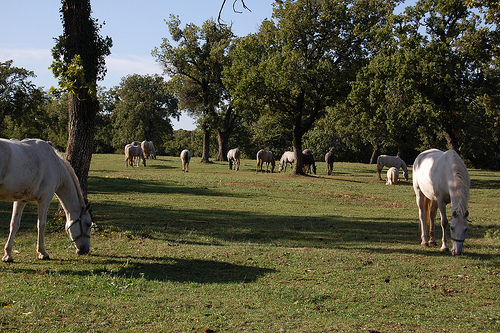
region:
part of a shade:
[222, 205, 262, 252]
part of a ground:
[292, 263, 322, 300]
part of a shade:
[222, 245, 261, 280]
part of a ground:
[343, 255, 397, 312]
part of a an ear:
[443, 202, 448, 214]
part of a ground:
[328, 267, 368, 308]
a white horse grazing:
[1, 133, 90, 263]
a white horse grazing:
[409, 145, 466, 254]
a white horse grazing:
[373, 153, 409, 184]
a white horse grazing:
[382, 162, 398, 185]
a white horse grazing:
[277, 149, 295, 172]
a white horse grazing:
[220, 145, 242, 170]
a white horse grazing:
[175, 145, 192, 168]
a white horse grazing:
[123, 142, 149, 167]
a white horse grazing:
[139, 134, 157, 161]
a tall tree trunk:
[62, 0, 99, 167]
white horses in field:
[0, 136, 474, 259]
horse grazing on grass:
[411, 147, 473, 260]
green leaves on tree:
[167, 17, 231, 110]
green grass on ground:
[2, 143, 497, 330]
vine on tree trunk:
[50, 22, 111, 111]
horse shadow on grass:
[11, 254, 278, 281]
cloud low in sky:
[2, 1, 276, 78]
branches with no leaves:
[215, 0, 254, 30]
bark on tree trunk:
[66, 93, 100, 165]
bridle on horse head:
[66, 211, 95, 246]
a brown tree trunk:
[52, 1, 102, 218]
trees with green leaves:
[0, 0, 498, 217]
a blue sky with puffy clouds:
[0, 0, 496, 132]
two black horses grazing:
[301, 144, 338, 179]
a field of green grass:
[2, 152, 498, 331]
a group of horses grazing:
[0, 137, 472, 264]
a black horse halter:
[64, 204, 94, 243]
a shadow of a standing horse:
[4, 250, 280, 287]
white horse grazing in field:
[409, 149, 471, 255]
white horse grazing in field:
[0, 135, 92, 265]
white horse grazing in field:
[375, 152, 411, 188]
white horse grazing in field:
[278, 151, 296, 177]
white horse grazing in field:
[303, 150, 320, 175]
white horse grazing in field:
[253, 148, 278, 173]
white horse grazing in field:
[223, 146, 243, 170]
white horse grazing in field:
[180, 149, 192, 171]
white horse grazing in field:
[122, 143, 149, 168]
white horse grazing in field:
[141, 140, 158, 158]